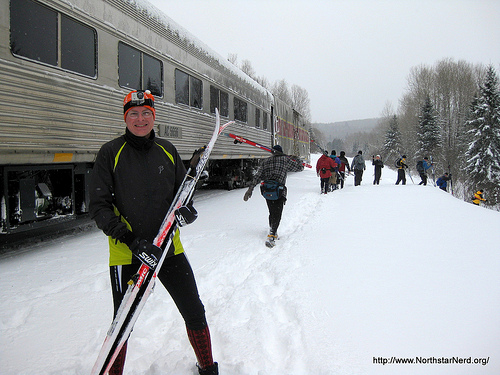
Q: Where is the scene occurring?
A: Next to railroad tracks.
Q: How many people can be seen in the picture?
A: 11.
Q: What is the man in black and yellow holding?
A: Skies.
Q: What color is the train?
A: Silver.